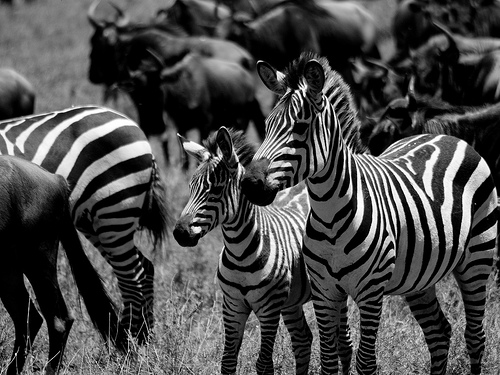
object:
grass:
[0, 0, 500, 375]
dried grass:
[0, 0, 499, 372]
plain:
[0, 0, 498, 375]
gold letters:
[170, 49, 357, 261]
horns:
[88, 0, 105, 33]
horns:
[120, 62, 134, 83]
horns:
[213, 0, 222, 21]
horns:
[244, 0, 259, 19]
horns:
[427, 16, 460, 65]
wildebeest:
[208, 0, 385, 84]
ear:
[175, 132, 213, 162]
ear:
[300, 59, 327, 103]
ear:
[217, 125, 240, 176]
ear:
[256, 60, 288, 96]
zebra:
[238, 52, 495, 373]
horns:
[144, 48, 163, 77]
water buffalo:
[81, 1, 236, 39]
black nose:
[241, 160, 267, 198]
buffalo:
[115, 53, 267, 171]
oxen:
[223, 0, 377, 71]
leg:
[24, 245, 76, 371]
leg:
[105, 212, 147, 336]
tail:
[137, 160, 176, 260]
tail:
[58, 174, 136, 362]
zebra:
[0, 110, 167, 340]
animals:
[0, 1, 499, 372]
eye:
[292, 120, 309, 135]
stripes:
[0, 104, 156, 345]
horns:
[105, 0, 132, 28]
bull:
[84, 14, 257, 86]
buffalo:
[366, 89, 488, 156]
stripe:
[306, 226, 372, 280]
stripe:
[383, 150, 473, 295]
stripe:
[373, 235, 416, 295]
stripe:
[338, 147, 350, 197]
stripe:
[305, 152, 341, 244]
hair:
[279, 47, 370, 158]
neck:
[305, 144, 362, 229]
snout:
[173, 222, 199, 247]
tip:
[173, 227, 185, 237]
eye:
[209, 186, 223, 196]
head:
[173, 125, 245, 248]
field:
[0, 0, 499, 375]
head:
[240, 52, 340, 210]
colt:
[172, 125, 352, 375]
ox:
[0, 69, 39, 117]